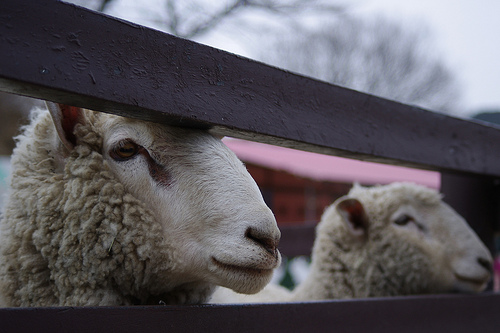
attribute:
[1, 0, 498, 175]
fence — wooden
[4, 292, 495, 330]
board — lowest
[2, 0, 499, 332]
fence — wooden, brown, low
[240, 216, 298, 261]
nose — brown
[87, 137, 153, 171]
eye — brown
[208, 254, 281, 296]
mouth — closed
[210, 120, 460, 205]
roof — red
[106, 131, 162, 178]
eye — black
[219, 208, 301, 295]
nose — small, sheep's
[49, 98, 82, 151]
ear — pink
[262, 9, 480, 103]
tree — bare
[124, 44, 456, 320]
fence — brown, wooden, board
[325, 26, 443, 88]
leaves — no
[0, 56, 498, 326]
sheep — white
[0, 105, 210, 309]
wool — white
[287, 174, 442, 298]
wool — white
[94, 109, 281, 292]
face — white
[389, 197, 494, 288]
face — white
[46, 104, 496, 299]
heads — poking through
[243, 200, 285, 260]
nose — brown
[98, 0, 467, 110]
trees — distant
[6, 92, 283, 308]
sheep — white